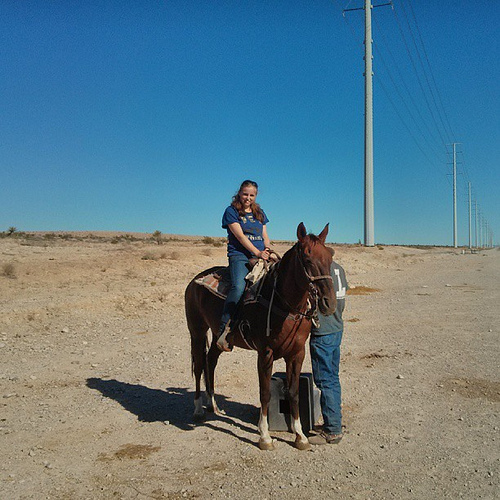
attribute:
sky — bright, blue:
[2, 1, 499, 248]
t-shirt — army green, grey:
[309, 260, 347, 335]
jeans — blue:
[308, 332, 344, 433]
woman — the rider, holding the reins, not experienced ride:
[217, 181, 279, 349]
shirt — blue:
[222, 205, 269, 254]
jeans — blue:
[223, 257, 267, 340]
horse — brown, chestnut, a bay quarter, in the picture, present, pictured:
[185, 222, 334, 451]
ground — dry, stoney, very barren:
[0, 230, 499, 496]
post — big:
[341, 1, 394, 247]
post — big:
[444, 139, 464, 249]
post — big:
[467, 180, 473, 244]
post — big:
[473, 198, 478, 251]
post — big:
[478, 204, 482, 247]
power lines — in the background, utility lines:
[335, 0, 499, 247]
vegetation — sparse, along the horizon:
[2, 224, 467, 247]